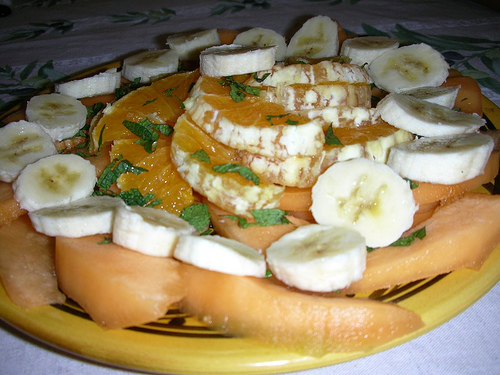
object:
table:
[0, 0, 500, 375]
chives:
[121, 120, 160, 155]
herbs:
[177, 203, 212, 232]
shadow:
[0, 322, 152, 373]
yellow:
[35, 313, 75, 340]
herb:
[390, 234, 415, 247]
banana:
[375, 92, 486, 138]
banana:
[366, 42, 450, 94]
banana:
[109, 206, 198, 259]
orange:
[238, 121, 414, 188]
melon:
[1, 206, 67, 308]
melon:
[442, 69, 484, 113]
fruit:
[51, 236, 186, 331]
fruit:
[183, 74, 326, 159]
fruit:
[167, 111, 285, 219]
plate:
[0, 36, 499, 373]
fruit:
[109, 137, 193, 221]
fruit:
[247, 60, 374, 87]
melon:
[175, 263, 424, 356]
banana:
[198, 42, 278, 77]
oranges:
[88, 68, 201, 153]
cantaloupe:
[329, 195, 500, 298]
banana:
[265, 225, 367, 294]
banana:
[307, 158, 416, 248]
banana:
[386, 133, 495, 186]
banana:
[171, 235, 267, 278]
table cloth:
[0, 3, 500, 375]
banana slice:
[27, 195, 123, 237]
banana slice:
[11, 153, 98, 213]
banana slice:
[0, 119, 59, 182]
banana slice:
[24, 91, 88, 143]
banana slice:
[54, 67, 123, 100]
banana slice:
[120, 47, 180, 83]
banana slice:
[167, 27, 223, 65]